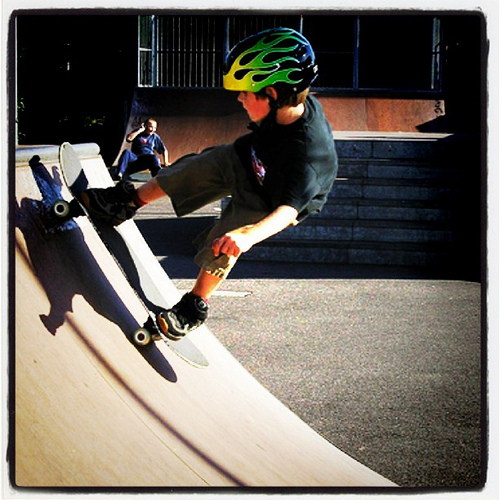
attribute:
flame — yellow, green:
[235, 37, 292, 94]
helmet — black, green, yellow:
[217, 30, 330, 93]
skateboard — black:
[64, 149, 196, 350]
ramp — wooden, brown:
[28, 115, 417, 495]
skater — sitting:
[129, 112, 179, 175]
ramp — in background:
[131, 92, 464, 210]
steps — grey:
[267, 162, 486, 272]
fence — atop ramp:
[124, 10, 432, 98]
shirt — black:
[250, 110, 345, 211]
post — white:
[135, 14, 169, 85]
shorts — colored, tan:
[159, 121, 262, 262]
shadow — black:
[23, 181, 169, 385]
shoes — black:
[64, 180, 199, 346]